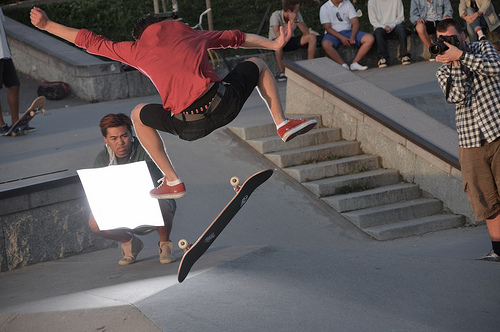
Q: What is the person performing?
A: Stunt.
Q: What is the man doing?
A: Crouching.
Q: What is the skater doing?
A: Jumping.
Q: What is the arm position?
A: Extended.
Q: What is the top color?
A: Red.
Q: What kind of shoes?
A: Tennis.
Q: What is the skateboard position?
A: Upside down.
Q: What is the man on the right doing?
A: Taking picture.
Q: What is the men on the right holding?
A: Camera.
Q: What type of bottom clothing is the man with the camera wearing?
A: Shorts.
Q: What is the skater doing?
A: Jumping.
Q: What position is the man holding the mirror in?
A: Crouching.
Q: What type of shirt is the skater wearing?
A: Long sleeve shirt.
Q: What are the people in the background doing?
A: Sitting.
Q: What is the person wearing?
A: White socks.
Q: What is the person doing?
A: A trick.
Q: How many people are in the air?
A: One.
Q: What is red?
A: Skateboarder's shirt.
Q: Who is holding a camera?
A: Man on right.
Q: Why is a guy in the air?
A: Guy is skateboarding.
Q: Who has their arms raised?
A: Skateboarder.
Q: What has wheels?
A: A skateboard.